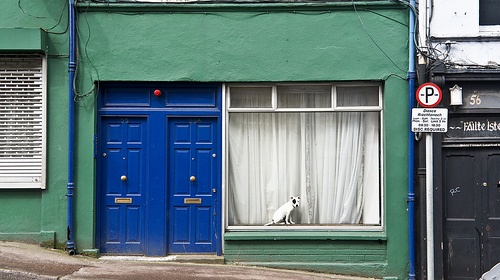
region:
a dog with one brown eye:
[252, 188, 314, 235]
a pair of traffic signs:
[410, 77, 457, 144]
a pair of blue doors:
[93, 98, 235, 260]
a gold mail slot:
[103, 190, 135, 211]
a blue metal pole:
[56, 23, 93, 241]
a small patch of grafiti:
[447, 177, 473, 203]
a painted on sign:
[456, 111, 498, 141]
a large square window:
[216, 60, 397, 258]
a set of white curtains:
[229, 79, 391, 245]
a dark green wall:
[13, 10, 445, 271]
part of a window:
[285, 142, 325, 192]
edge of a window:
[373, 165, 385, 195]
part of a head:
[292, 197, 308, 218]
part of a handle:
[184, 168, 196, 190]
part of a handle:
[342, 148, 379, 171]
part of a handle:
[186, 223, 211, 250]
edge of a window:
[331, 229, 365, 249]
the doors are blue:
[97, 132, 196, 256]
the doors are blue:
[153, 165, 229, 271]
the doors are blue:
[128, 112, 237, 252]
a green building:
[0, 5, 416, 270]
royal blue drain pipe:
[63, 1, 85, 261]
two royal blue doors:
[94, 79, 220, 257]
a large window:
[225, 82, 381, 230]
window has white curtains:
[228, 91, 376, 203]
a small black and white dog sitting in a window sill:
[258, 183, 339, 231]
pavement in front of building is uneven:
[4, 230, 385, 278]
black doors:
[425, 68, 499, 278]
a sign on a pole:
[408, 76, 453, 278]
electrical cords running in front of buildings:
[21, 0, 498, 96]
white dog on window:
[282, 177, 346, 231]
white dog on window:
[258, 190, 296, 247]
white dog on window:
[215, 165, 303, 243]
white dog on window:
[242, 171, 330, 251]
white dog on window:
[232, 194, 314, 269]